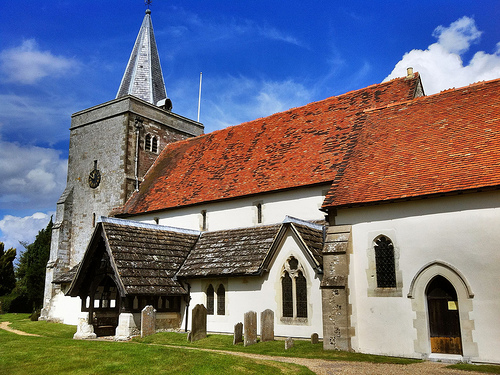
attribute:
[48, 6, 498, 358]
church — old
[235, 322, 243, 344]
headstone — grey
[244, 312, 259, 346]
headstone — grey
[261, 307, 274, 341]
headstone — grey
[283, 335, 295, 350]
headstone — grey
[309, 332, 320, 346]
headstone — grey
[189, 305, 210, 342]
headstone — grey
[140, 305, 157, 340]
headstone — grey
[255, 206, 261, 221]
window — small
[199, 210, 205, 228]
window — small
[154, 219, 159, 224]
window — small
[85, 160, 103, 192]
clock — black, gold, circular, large, dark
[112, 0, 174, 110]
steeple — tall, gray, shingled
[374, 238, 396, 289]
window — narrow, arched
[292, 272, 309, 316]
window — narrow, arched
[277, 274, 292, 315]
window — narrow, arched